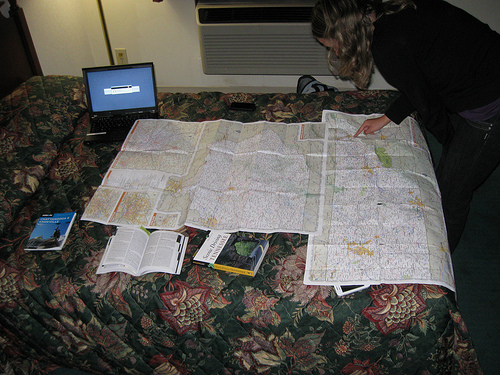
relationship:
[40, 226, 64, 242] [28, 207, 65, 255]
travel guide book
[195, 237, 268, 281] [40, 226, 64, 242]
guidebook for travel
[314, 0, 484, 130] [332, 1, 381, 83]
female's long hair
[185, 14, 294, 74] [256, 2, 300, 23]
unit for air conditioning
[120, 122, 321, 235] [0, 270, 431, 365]
map on bed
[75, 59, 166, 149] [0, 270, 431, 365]
computers on bed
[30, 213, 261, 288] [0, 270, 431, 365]
books on bed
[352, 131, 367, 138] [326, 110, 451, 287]
pointing on map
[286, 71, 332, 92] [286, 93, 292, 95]
bag on ground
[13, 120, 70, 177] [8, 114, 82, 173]
flower drawing on comforter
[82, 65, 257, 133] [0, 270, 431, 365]
computers are on top of bed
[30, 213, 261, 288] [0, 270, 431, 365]
books are on top of bed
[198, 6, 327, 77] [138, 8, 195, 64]
air conditioner on wall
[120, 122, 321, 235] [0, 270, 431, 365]
map on top of bed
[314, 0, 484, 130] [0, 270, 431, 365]
woman standing by bed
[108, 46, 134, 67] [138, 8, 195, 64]
electrical outlet on wall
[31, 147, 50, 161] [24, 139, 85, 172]
flower on top of bed spread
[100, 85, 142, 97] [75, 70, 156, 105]
design on top of screen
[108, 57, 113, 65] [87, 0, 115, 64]
part of lamp post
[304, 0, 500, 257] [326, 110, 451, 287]
female's reading map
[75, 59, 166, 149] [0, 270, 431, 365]
computers on top of bed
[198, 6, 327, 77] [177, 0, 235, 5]
air conditioner hanging on window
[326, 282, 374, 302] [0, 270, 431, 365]
brochure on top of bed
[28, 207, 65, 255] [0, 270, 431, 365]
book lying on top of bed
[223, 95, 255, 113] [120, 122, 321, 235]
cell phone under map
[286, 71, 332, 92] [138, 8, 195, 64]
backpack leaning against wall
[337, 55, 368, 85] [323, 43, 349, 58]
brown hair hanging over face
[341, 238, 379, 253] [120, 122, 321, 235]
markings on top of map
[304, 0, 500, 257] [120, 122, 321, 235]
female's leaning over map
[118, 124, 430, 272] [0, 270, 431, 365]
two maps on top of bed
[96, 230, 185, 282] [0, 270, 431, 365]
open book on top of bed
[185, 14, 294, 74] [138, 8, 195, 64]
ac unit attached to wall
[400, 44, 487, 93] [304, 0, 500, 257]
black sweater on female's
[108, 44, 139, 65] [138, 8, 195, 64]
electrical outlet attached to wall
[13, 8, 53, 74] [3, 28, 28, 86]
edge of headboard